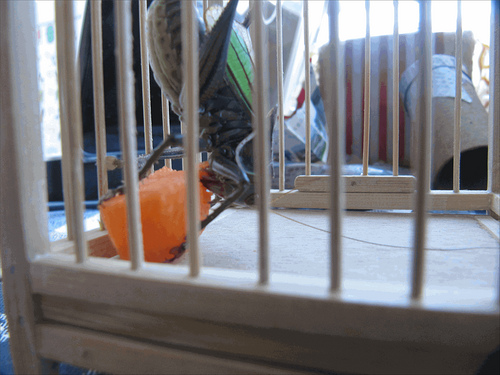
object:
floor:
[0, 204, 113, 369]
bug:
[93, 0, 343, 259]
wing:
[195, 4, 287, 135]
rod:
[237, 46, 283, 238]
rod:
[308, 27, 365, 242]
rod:
[413, 25, 455, 231]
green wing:
[235, 41, 252, 89]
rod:
[361, 0, 372, 179]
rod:
[244, 1, 296, 292]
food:
[101, 164, 196, 254]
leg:
[169, 159, 250, 248]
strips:
[344, 36, 455, 165]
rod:
[270, 1, 287, 188]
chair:
[320, 34, 473, 176]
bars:
[73, 31, 469, 283]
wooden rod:
[447, 2, 465, 191]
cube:
[97, 162, 212, 262]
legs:
[201, 0, 239, 95]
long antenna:
[343, 233, 411, 253]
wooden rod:
[387, 0, 408, 175]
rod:
[412, 0, 432, 302]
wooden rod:
[80, 257, 202, 312]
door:
[282, 31, 433, 203]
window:
[329, 0, 498, 35]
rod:
[408, 0, 434, 300]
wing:
[208, 22, 258, 114]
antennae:
[439, 233, 499, 269]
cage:
[4, 6, 499, 372]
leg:
[116, 126, 183, 190]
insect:
[97, 0, 255, 256]